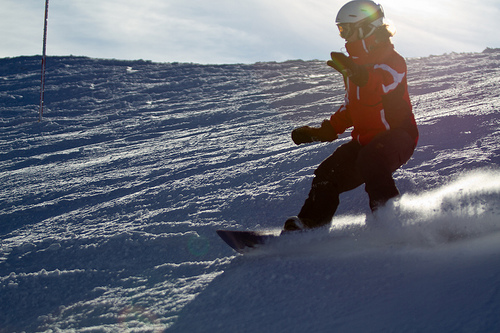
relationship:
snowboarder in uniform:
[306, 4, 426, 274] [293, 23, 421, 232]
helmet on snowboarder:
[335, 0, 387, 39] [284, 0, 420, 233]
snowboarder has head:
[284, 0, 420, 233] [334, 0, 388, 49]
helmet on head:
[335, 0, 387, 39] [334, 0, 388, 49]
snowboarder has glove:
[284, 0, 420, 233] [289, 121, 321, 145]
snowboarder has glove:
[284, 0, 420, 233] [325, 50, 369, 85]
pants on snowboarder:
[284, 146, 396, 231] [284, 0, 420, 233]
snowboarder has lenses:
[284, 0, 420, 233] [320, 15, 352, 41]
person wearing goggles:
[280, 0, 424, 234] [335, 14, 369, 38]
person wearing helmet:
[280, 0, 424, 234] [330, 0, 390, 41]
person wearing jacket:
[280, 0, 424, 234] [313, 42, 413, 138]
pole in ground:
[36, 0, 53, 117] [0, 52, 498, 331]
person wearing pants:
[280, 0, 424, 234] [297, 129, 421, 216]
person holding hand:
[280, 0, 424, 234] [326, 26, 373, 76]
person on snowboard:
[280, 0, 424, 234] [215, 222, 274, 254]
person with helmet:
[280, 0, 424, 234] [336, 0, 413, 47]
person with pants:
[280, 0, 424, 234] [293, 125, 423, 229]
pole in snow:
[38, 0, 50, 118] [23, 120, 78, 142]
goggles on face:
[337, 22, 369, 34] [335, 22, 357, 45]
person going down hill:
[280, 0, 424, 234] [12, 68, 263, 295]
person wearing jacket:
[280, 0, 424, 234] [306, 24, 426, 168]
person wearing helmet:
[280, 0, 424, 234] [335, 1, 385, 26]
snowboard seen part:
[214, 222, 277, 259] [235, 226, 260, 236]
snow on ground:
[0, 45, 499, 332] [347, 137, 385, 192]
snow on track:
[0, 45, 499, 332] [66, 130, 196, 204]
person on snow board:
[221, 0, 488, 267] [226, 217, 294, 258]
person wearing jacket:
[280, 0, 424, 234] [323, 36, 415, 144]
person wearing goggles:
[280, 0, 424, 234] [336, 22, 358, 38]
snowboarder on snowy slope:
[284, 0, 420, 233] [10, 50, 499, 313]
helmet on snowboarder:
[332, 6, 410, 58] [264, 10, 442, 260]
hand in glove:
[326, 57, 367, 87] [326, 47, 373, 92]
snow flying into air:
[0, 45, 499, 332] [264, 173, 498, 273]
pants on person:
[297, 140, 415, 229] [280, 0, 424, 234]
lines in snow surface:
[38, 121, 221, 236] [30, 70, 237, 246]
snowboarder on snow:
[284, 0, 420, 233] [0, 45, 497, 331]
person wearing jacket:
[280, 0, 424, 234] [314, 39, 424, 161]